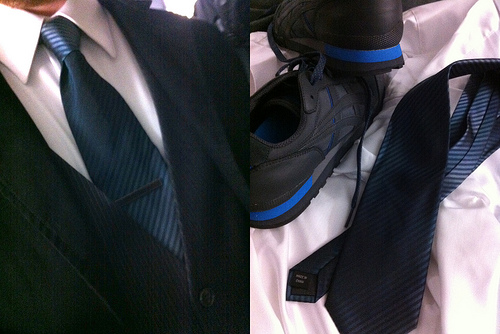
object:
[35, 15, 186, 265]
tie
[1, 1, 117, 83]
collar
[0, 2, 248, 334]
man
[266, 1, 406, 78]
shoe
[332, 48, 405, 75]
heel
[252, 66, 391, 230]
shoe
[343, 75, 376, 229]
lace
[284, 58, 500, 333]
tie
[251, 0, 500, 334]
cloth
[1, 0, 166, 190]
shirt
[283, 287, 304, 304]
tip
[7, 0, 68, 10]
chin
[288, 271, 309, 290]
tag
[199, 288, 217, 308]
button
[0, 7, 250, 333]
blazer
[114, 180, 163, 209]
tie clip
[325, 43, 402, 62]
stripe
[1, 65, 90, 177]
wrinkle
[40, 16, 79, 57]
knot